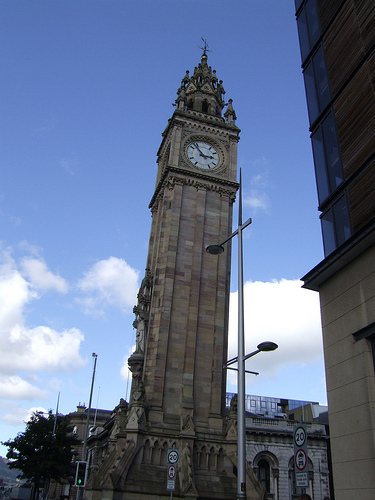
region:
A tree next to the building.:
[25, 414, 64, 495]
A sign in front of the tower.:
[167, 443, 192, 499]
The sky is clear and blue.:
[19, 139, 139, 296]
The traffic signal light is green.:
[68, 454, 97, 496]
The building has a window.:
[312, 194, 366, 256]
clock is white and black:
[185, 135, 222, 173]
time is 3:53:
[188, 136, 221, 172]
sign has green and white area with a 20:
[294, 427, 305, 448]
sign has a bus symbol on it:
[295, 448, 305, 470]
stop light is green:
[74, 459, 84, 486]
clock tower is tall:
[105, 35, 260, 497]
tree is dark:
[6, 410, 80, 496]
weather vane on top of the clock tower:
[195, 35, 211, 59]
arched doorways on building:
[249, 448, 277, 498]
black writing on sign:
[295, 472, 305, 488]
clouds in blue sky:
[1, 1, 326, 456]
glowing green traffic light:
[72, 459, 87, 499]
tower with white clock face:
[133, 39, 241, 432]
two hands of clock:
[187, 141, 218, 167]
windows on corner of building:
[293, 0, 370, 259]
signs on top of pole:
[291, 423, 311, 498]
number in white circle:
[167, 450, 179, 463]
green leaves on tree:
[6, 409, 81, 486]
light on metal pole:
[204, 168, 253, 497]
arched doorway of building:
[252, 450, 280, 496]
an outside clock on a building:
[178, 129, 243, 186]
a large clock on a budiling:
[183, 137, 209, 178]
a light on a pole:
[249, 324, 275, 374]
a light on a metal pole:
[247, 336, 275, 361]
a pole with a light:
[242, 336, 280, 371]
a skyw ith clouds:
[5, 245, 149, 394]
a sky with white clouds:
[17, 239, 156, 370]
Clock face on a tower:
[176, 137, 227, 174]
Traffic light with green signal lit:
[69, 459, 85, 488]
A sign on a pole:
[164, 448, 178, 496]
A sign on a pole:
[291, 420, 309, 498]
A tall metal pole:
[236, 202, 246, 493]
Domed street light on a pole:
[259, 339, 279, 353]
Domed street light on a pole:
[205, 243, 223, 255]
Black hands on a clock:
[193, 143, 213, 159]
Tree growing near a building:
[3, 411, 71, 499]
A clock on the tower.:
[181, 125, 237, 182]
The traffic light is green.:
[75, 456, 96, 494]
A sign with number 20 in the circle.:
[166, 447, 184, 459]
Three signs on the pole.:
[283, 429, 318, 498]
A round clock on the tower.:
[183, 136, 220, 170]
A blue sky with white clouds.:
[0, 0, 327, 455]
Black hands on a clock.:
[191, 141, 214, 160]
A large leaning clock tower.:
[124, 37, 240, 499]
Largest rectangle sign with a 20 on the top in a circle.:
[292, 423, 308, 488]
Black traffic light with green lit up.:
[75, 460, 87, 485]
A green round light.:
[76, 479, 81, 483]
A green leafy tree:
[0, 407, 83, 499]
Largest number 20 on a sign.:
[294, 430, 304, 442]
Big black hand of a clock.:
[192, 141, 207, 161]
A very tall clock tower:
[133, 56, 255, 314]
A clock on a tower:
[161, 100, 255, 185]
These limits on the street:
[150, 447, 192, 488]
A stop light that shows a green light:
[50, 435, 125, 498]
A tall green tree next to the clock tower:
[9, 402, 79, 493]